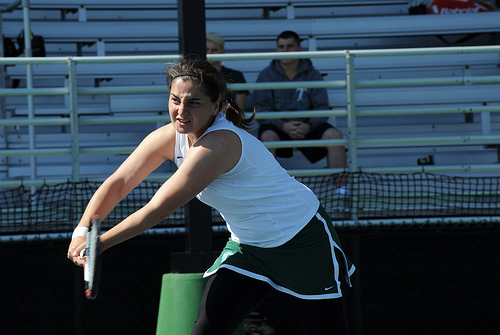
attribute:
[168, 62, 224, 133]
head — on woman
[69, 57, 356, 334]
tennis player — playing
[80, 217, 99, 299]
racket — tennis, black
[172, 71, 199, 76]
headband — black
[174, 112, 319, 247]
tanktop — white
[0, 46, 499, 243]
fence — metal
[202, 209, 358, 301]
skirt — black, white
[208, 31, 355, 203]
men — watching, sitting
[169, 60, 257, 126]
hair — brown, dark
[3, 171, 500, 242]
mesh — black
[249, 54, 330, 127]
hoodie — grey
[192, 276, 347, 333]
leggings — black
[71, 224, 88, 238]
wristband — on wrist, white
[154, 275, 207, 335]
base — green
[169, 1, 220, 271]
pole — black